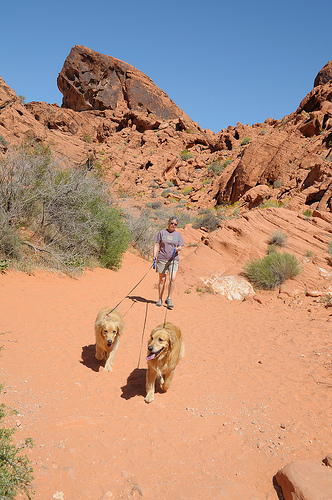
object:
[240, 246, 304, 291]
bush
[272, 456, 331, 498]
rock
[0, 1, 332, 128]
sky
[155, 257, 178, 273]
shorts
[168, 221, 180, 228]
sunglasses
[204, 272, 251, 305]
rocks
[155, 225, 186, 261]
shirt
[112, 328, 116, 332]
eye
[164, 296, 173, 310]
shoe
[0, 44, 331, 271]
mountains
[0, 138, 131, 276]
bushes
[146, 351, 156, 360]
tongue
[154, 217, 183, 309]
person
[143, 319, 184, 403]
dog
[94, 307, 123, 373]
dog